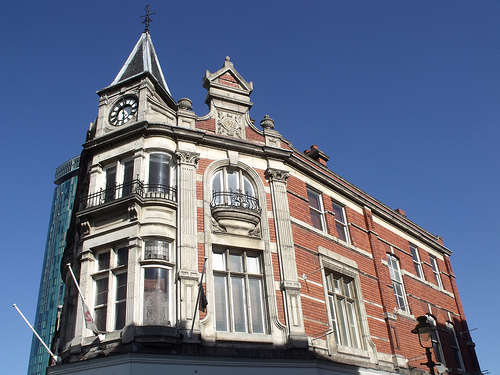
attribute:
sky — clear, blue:
[0, 1, 500, 374]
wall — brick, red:
[288, 164, 484, 374]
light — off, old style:
[417, 326, 432, 340]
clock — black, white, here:
[109, 94, 139, 127]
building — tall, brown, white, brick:
[46, 4, 483, 374]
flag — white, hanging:
[199, 285, 209, 312]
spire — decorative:
[265, 169, 309, 347]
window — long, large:
[231, 274, 248, 334]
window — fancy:
[146, 266, 170, 326]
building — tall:
[27, 155, 80, 374]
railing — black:
[79, 175, 179, 202]